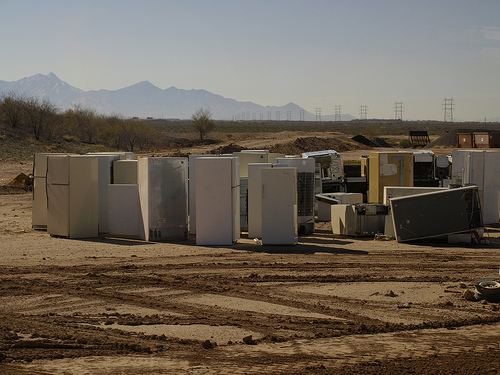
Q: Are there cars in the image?
A: No, there are no cars.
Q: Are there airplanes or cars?
A: No, there are no cars or airplanes.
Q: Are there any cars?
A: No, there are no cars.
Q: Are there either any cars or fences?
A: No, there are no cars or fences.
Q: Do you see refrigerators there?
A: Yes, there is a refrigerator.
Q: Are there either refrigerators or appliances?
A: Yes, there is a refrigerator.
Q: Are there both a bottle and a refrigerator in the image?
A: No, there is a refrigerator but no bottles.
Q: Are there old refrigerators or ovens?
A: Yes, there is an old refrigerator.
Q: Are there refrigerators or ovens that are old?
A: Yes, the refrigerator is old.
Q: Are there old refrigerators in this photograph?
A: Yes, there is an old refrigerator.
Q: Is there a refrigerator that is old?
A: Yes, there is a refrigerator that is old.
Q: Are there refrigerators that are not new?
A: Yes, there is a old refrigerator.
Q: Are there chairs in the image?
A: No, there are no chairs.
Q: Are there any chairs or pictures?
A: No, there are no chairs or pictures.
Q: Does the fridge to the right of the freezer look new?
A: No, the freezer is old.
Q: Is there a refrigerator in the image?
A: Yes, there is a refrigerator.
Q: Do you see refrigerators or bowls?
A: Yes, there is a refrigerator.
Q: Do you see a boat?
A: No, there are no boats.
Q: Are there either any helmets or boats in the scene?
A: No, there are no boats or helmets.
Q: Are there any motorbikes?
A: No, there are no motorbikes.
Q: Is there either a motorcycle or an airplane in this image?
A: No, there are no motorcycles or airplanes.